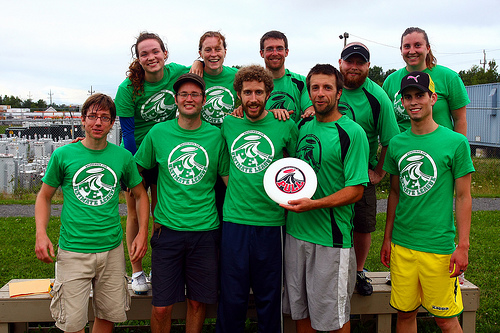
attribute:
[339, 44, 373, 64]
visor — black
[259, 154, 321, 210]
frisbee — round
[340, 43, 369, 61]
baseball cap — blue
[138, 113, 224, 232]
uniform — green, white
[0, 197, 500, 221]
trail — behind, paved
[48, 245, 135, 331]
shorts — khaki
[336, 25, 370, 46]
pole — utility, carrying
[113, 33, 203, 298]
girl — forward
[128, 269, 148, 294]
shoe — white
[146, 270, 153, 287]
shoe — white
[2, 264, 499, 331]
bench — long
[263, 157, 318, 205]
frisbee — white, red, black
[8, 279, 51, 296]
paper — orange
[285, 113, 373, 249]
shirt — green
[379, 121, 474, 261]
shirt — green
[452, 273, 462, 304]
bolt — black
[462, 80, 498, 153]
shipping container — light blue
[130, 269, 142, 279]
white flap — big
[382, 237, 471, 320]
shorts — yellow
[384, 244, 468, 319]
shorts — yellow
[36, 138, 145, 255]
shirt — green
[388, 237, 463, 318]
shorts — yellow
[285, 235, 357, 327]
shorts — gray